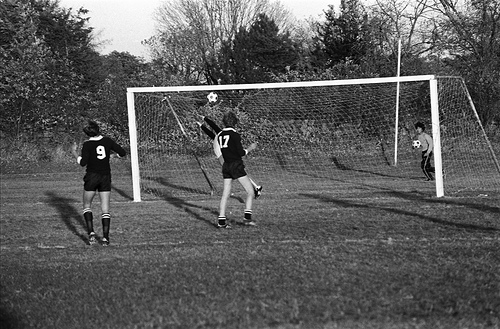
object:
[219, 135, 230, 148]
17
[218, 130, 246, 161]
jersey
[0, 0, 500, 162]
background trees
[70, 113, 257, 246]
two players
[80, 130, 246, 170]
black shirts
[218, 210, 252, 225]
socks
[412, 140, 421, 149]
ball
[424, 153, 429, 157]
hand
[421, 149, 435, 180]
pants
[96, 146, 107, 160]
9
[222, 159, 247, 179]
shorts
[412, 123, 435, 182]
boy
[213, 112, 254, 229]
boy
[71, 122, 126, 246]
boy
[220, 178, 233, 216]
leg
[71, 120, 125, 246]
woman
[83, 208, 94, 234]
sock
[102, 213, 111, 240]
sock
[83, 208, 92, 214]
stripe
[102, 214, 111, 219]
stripe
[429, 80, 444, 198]
pole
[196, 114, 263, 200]
goalie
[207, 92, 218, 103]
ball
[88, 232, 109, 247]
sneakers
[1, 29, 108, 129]
bushes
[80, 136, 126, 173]
shirt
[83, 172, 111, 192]
shorts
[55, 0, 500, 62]
sky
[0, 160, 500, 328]
ground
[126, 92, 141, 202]
pole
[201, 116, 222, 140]
shirt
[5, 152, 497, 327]
field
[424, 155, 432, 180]
stripe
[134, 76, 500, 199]
net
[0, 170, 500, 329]
soccer field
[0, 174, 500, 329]
grass